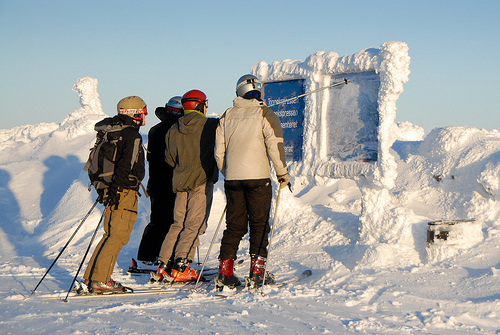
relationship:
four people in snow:
[82, 73, 291, 295] [2, 250, 495, 332]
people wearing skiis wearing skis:
[56, 51, 307, 327] [6, 272, 316, 302]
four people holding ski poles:
[82, 73, 291, 295] [22, 191, 112, 305]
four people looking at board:
[82, 73, 291, 295] [254, 73, 307, 170]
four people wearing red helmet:
[82, 73, 291, 295] [181, 89, 207, 114]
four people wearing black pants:
[82, 73, 291, 295] [138, 183, 182, 275]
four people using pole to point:
[82, 73, 291, 295] [263, 71, 371, 112]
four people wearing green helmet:
[82, 73, 291, 295] [107, 89, 158, 128]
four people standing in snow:
[70, 66, 301, 332] [6, 74, 496, 330]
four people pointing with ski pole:
[82, 73, 291, 295] [264, 73, 361, 109]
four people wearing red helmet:
[82, 73, 291, 295] [174, 80, 220, 123]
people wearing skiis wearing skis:
[19, 73, 313, 302] [0, 263, 320, 303]